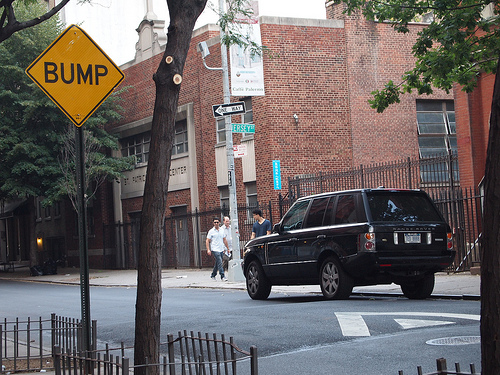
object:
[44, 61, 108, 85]
bump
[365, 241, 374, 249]
taillight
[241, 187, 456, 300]
car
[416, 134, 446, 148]
windows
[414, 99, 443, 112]
windows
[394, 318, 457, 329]
markings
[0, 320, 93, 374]
fence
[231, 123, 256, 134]
sign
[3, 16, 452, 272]
brick building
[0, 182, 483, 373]
street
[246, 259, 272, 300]
tire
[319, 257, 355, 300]
tire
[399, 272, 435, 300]
tire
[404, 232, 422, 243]
tag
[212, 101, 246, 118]
sign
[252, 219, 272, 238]
blue shirt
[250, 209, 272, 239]
people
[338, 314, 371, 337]
line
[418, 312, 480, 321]
line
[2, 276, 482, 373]
pavement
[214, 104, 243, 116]
arrow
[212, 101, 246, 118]
square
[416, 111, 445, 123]
windows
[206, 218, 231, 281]
people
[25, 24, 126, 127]
sign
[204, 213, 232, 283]
two people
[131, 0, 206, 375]
tree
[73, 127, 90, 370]
pole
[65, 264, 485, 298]
sidewalk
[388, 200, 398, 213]
sticker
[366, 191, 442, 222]
window